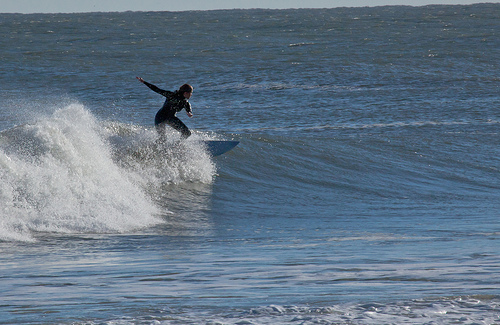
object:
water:
[0, 2, 499, 325]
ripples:
[0, 2, 499, 325]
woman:
[133, 76, 192, 147]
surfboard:
[179, 139, 243, 157]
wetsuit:
[143, 81, 193, 145]